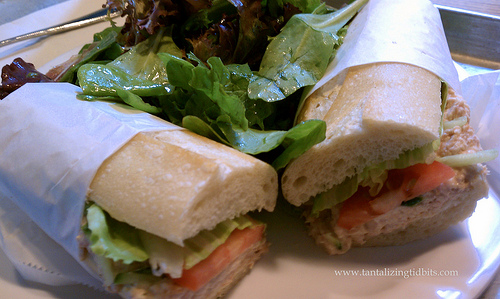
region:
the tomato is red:
[333, 160, 458, 235]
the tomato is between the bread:
[283, 75, 485, 255]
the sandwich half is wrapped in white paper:
[2, 75, 277, 297]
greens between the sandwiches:
[81, 3, 363, 158]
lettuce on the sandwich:
[71, 200, 159, 262]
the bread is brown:
[91, 131, 280, 233]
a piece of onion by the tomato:
[437, 143, 499, 166]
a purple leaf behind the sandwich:
[0, 55, 51, 92]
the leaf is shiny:
[78, 49, 200, 93]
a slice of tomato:
[328, 158, 451, 234]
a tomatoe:
[344, 173, 434, 220]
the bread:
[323, 72, 414, 149]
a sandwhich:
[118, 158, 265, 297]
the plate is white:
[263, 258, 338, 296]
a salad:
[136, 53, 286, 108]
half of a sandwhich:
[321, 97, 467, 222]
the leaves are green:
[178, 44, 268, 133]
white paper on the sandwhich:
[11, 98, 93, 183]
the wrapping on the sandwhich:
[378, 32, 443, 61]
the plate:
[265, 253, 335, 295]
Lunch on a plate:
[22, 6, 480, 297]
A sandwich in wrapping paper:
[314, 15, 497, 222]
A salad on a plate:
[88, 6, 351, 142]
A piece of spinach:
[253, 14, 330, 96]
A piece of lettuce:
[188, 68, 263, 138]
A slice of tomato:
[335, 165, 451, 219]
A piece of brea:
[309, 67, 469, 165]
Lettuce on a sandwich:
[78, 203, 243, 270]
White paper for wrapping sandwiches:
[7, 87, 80, 239]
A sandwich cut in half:
[53, 48, 463, 297]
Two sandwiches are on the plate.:
[3, 0, 485, 297]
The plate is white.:
[0, 17, 497, 297]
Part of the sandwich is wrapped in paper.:
[1, 66, 278, 293]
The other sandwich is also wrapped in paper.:
[280, 8, 485, 258]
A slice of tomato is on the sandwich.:
[166, 222, 256, 290]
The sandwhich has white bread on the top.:
[272, 63, 442, 199]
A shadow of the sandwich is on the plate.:
[275, 205, 465, 266]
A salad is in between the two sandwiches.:
[65, 1, 335, 151]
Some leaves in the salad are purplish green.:
[115, 1, 278, 53]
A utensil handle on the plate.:
[0, 0, 145, 61]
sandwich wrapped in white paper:
[4, 74, 276, 297]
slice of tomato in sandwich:
[172, 213, 257, 284]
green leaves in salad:
[101, 3, 360, 178]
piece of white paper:
[5, 60, 178, 280]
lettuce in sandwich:
[74, 193, 153, 278]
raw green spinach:
[82, 13, 222, 110]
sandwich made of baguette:
[282, 70, 493, 266]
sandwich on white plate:
[227, 5, 496, 295]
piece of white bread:
[89, 120, 281, 244]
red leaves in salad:
[117, 3, 304, 65]